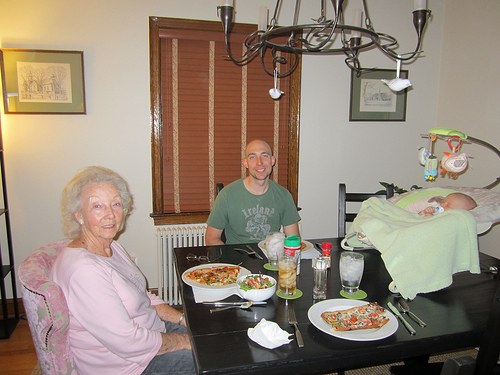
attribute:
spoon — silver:
[397, 297, 424, 325]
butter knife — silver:
[387, 300, 415, 337]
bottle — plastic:
[281, 226, 305, 281]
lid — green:
[283, 233, 303, 252]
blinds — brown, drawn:
[161, 32, 253, 155]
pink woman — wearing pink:
[48, 167, 191, 374]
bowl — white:
[236, 266, 277, 307]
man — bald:
[179, 137, 301, 250]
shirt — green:
[198, 177, 308, 244]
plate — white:
[176, 254, 254, 288]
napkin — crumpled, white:
[244, 315, 297, 352]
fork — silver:
[289, 305, 315, 345]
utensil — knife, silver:
[353, 267, 460, 363]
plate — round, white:
[300, 247, 423, 367]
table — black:
[204, 207, 306, 359]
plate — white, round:
[182, 262, 252, 292]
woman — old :
[47, 160, 192, 361]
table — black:
[170, 232, 498, 372]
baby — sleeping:
[376, 185, 493, 234]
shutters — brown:
[167, 37, 287, 198]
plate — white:
[307, 297, 402, 341]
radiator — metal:
[135, 223, 208, 305]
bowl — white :
[235, 272, 277, 302]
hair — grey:
[58, 164, 131, 239]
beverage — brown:
[274, 260, 296, 292]